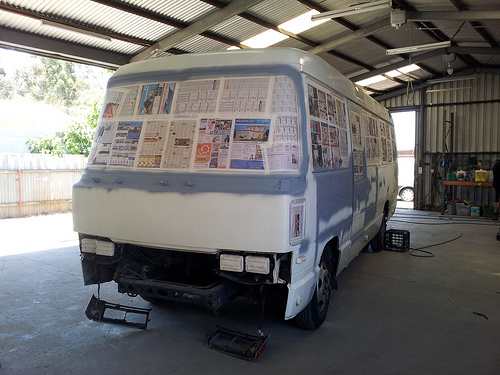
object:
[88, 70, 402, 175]
newspaper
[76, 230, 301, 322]
front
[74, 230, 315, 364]
off van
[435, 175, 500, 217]
table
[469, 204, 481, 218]
boxes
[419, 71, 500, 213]
corrugated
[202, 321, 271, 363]
left side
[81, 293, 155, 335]
right side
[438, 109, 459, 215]
equiptment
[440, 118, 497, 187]
painting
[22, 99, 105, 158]
trees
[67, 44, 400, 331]
old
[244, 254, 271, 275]
headlights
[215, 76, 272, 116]
newspapers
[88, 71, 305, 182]
windshield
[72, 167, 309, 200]
blue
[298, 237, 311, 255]
spots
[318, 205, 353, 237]
white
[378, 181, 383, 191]
spots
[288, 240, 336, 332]
tires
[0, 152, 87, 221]
fence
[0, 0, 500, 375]
garage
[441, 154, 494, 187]
rack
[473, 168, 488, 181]
tools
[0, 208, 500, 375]
concrete